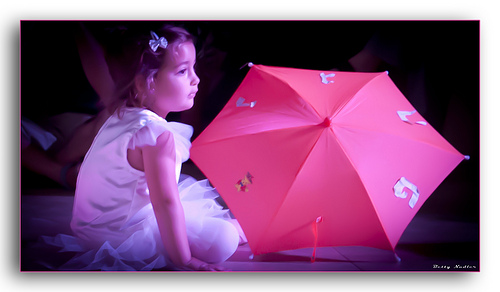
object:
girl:
[28, 26, 243, 270]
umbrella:
[192, 61, 464, 254]